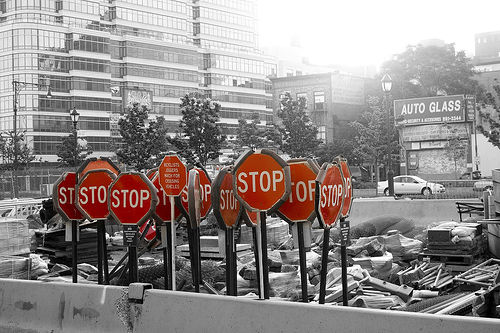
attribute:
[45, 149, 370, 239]
stop signs — new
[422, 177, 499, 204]
gate — metal, Portable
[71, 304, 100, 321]
stain — fish shaped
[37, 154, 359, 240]
signs — white, red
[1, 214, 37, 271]
pallet — Shrink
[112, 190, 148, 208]
letters — white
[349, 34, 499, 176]
building — Brick  , auto repair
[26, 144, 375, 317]
signs — red, white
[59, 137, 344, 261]
stop signs — red, white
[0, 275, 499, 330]
cement barracade — Damaged, cement 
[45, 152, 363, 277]
signs — white, red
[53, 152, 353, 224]
signs — white, red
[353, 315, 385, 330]
bridge — small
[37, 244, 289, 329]
bridge — small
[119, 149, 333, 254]
signs — bunch, stop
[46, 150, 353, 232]
stop signs — red, white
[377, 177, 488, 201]
bridge — small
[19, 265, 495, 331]
bridge — small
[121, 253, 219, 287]
fence — Rolled up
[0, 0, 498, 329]
yard — supply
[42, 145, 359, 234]
stop signs — red , white 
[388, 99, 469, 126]
advertisement sign — Rectangular 